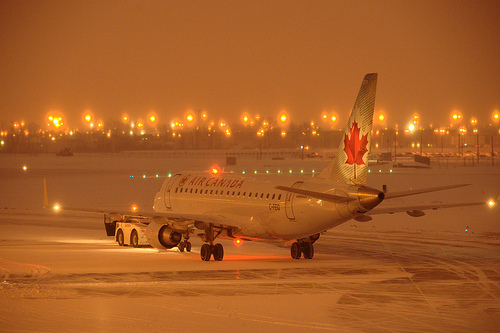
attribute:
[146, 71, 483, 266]
plane — large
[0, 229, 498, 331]
tarmac — snowy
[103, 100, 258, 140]
lights — bright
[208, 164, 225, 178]
light — overhead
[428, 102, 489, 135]
light — overhead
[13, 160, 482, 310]
runway — snowy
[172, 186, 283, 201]
window — small